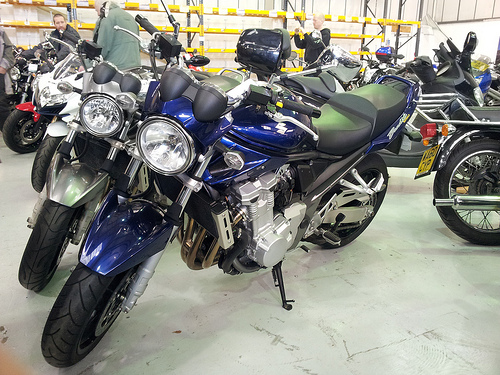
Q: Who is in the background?
A: Over two men.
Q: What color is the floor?
A: Green or grey.